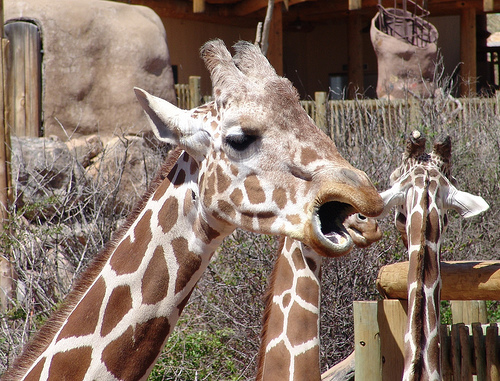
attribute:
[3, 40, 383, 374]
giraffe — enclosed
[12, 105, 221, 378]
neck — brown, white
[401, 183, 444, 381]
neck — brown, white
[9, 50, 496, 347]
branches — dry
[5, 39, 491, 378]
giraffes — located outside, outside in enclosure